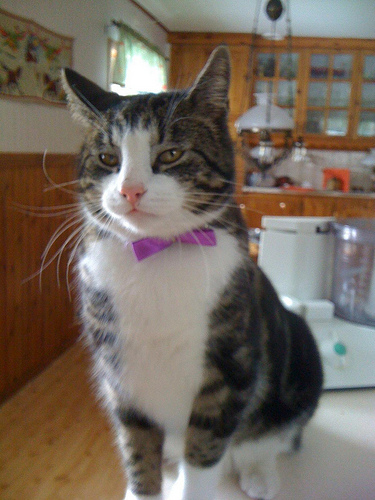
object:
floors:
[1, 343, 122, 500]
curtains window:
[104, 18, 171, 94]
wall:
[2, 0, 170, 409]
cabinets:
[168, 27, 374, 150]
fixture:
[234, 0, 305, 185]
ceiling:
[128, 0, 374, 40]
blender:
[256, 214, 374, 392]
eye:
[154, 145, 188, 173]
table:
[5, 322, 126, 499]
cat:
[18, 43, 325, 499]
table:
[159, 388, 372, 500]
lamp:
[233, 0, 303, 188]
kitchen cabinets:
[237, 191, 375, 238]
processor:
[256, 214, 335, 322]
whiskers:
[13, 147, 114, 303]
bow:
[131, 227, 218, 264]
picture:
[3, 9, 76, 109]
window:
[246, 49, 304, 132]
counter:
[125, 386, 374, 499]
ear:
[186, 46, 231, 109]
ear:
[60, 64, 119, 129]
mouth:
[121, 205, 155, 220]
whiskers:
[154, 175, 267, 307]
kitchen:
[0, 0, 373, 499]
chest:
[81, 233, 239, 430]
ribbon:
[130, 228, 216, 263]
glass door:
[251, 44, 299, 133]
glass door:
[299, 44, 356, 141]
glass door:
[354, 55, 374, 137]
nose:
[119, 179, 144, 204]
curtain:
[106, 22, 171, 94]